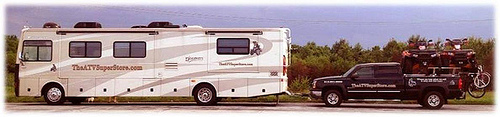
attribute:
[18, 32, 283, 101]
bus — white, tan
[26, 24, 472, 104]
vehicles — large, super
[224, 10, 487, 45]
sky — gray, blue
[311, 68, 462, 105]
truck — black, big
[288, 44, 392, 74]
trees — tall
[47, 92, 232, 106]
wheels — silver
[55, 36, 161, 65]
windows — trimmed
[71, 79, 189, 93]
squares — black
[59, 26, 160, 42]
bumper — silver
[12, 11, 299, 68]
camper — long, white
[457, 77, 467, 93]
tailights — red